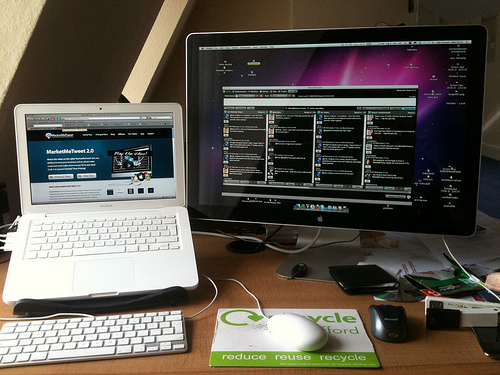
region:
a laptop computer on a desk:
[13, 92, 198, 317]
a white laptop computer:
[11, 96, 201, 301]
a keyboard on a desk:
[1, 308, 198, 361]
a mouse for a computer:
[246, 295, 336, 360]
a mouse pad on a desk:
[211, 304, 368, 371]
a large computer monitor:
[178, 15, 497, 244]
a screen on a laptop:
[16, 102, 188, 200]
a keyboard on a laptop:
[21, 213, 181, 266]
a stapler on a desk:
[421, 287, 494, 339]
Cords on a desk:
[196, 213, 335, 263]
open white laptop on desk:
[2, 95, 203, 311]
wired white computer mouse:
[210, 277, 338, 357]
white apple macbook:
[2, 100, 203, 310]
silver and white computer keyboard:
[1, 308, 198, 373]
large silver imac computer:
[171, 20, 492, 292]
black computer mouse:
[356, 298, 416, 347]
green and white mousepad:
[201, 290, 383, 372]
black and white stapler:
[421, 290, 498, 334]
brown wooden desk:
[2, 220, 497, 374]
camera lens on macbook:
[93, 104, 109, 114]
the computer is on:
[253, 74, 395, 184]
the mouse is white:
[261, 303, 331, 353]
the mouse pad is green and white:
[226, 316, 268, 357]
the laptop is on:
[55, 128, 131, 182]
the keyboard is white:
[6, 318, 152, 344]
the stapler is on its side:
[420, 290, 485, 333]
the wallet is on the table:
[336, 256, 383, 301]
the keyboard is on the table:
[149, 312, 201, 354]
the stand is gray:
[288, 248, 330, 273]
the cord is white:
[225, 265, 257, 308]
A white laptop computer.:
[6, 99, 198, 296]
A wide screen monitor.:
[184, 25, 494, 253]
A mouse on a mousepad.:
[223, 293, 380, 370]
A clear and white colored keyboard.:
[3, 315, 187, 367]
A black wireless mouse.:
[360, 299, 417, 344]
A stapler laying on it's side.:
[415, 291, 498, 335]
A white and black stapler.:
[424, 292, 495, 336]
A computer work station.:
[11, 23, 475, 360]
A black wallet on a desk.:
[325, 255, 398, 295]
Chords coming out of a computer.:
[248, 218, 332, 260]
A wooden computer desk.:
[1, 223, 491, 365]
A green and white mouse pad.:
[205, 297, 380, 369]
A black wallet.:
[325, 261, 392, 291]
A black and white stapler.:
[420, 295, 495, 325]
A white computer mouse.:
[255, 301, 327, 346]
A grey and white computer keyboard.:
[0, 307, 190, 362]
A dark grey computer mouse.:
[366, 295, 407, 342]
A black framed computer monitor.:
[186, 25, 490, 241]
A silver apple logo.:
[315, 214, 325, 224]